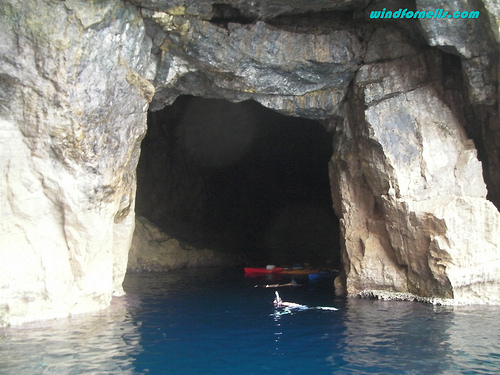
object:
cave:
[121, 93, 347, 301]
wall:
[328, 99, 496, 299]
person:
[272, 290, 311, 310]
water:
[0, 269, 499, 375]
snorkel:
[274, 290, 281, 308]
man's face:
[273, 296, 283, 307]